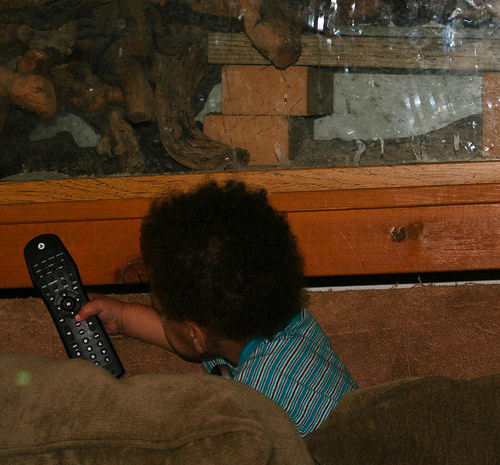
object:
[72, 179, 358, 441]
boy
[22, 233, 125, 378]
remote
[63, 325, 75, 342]
buttons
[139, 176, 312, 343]
hair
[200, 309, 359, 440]
shirt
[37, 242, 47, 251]
logo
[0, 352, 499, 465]
couch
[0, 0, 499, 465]
room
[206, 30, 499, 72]
wood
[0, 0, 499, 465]
background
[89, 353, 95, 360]
white numbers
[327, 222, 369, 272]
scratch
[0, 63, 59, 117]
logs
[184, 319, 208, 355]
ear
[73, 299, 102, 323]
thumb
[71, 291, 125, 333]
boy's hand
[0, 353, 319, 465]
pillow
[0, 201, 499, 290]
wood case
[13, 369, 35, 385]
spot